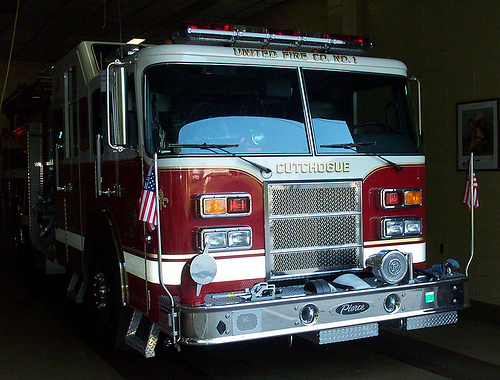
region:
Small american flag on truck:
[136, 153, 182, 358]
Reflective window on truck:
[139, 68, 425, 159]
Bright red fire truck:
[11, 19, 492, 379]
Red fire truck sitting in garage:
[9, 11, 494, 360]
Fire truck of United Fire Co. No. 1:
[94, 17, 478, 367]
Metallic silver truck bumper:
[169, 266, 482, 362]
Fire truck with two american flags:
[65, 19, 496, 369]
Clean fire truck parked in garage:
[26, 13, 493, 374]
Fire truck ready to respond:
[46, 22, 478, 363]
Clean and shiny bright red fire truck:
[5, 11, 496, 336]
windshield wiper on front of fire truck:
[156, 128, 278, 188]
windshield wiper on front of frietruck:
[316, 133, 409, 175]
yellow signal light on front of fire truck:
[197, 180, 229, 220]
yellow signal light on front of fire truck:
[403, 182, 425, 212]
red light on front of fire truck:
[378, 177, 404, 213]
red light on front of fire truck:
[226, 188, 254, 218]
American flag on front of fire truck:
[136, 142, 176, 305]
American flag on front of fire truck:
[449, 130, 490, 322]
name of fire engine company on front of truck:
[228, 32, 378, 80]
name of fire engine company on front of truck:
[262, 144, 408, 211]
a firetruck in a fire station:
[8, 9, 491, 364]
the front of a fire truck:
[138, 22, 488, 354]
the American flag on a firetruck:
[131, 148, 166, 249]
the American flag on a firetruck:
[463, 143, 483, 233]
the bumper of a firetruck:
[176, 272, 473, 352]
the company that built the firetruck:
[326, 296, 373, 321]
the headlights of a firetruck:
[199, 227, 256, 248]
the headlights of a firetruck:
[378, 218, 432, 241]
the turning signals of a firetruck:
[194, 190, 258, 220]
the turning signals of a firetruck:
[378, 183, 425, 208]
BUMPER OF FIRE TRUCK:
[177, 276, 478, 343]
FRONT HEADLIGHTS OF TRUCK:
[197, 221, 254, 247]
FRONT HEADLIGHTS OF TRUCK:
[380, 215, 430, 235]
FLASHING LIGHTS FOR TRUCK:
[196, 186, 253, 216]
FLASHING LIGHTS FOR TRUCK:
[375, 185, 425, 210]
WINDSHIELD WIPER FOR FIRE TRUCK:
[156, 130, 246, 155]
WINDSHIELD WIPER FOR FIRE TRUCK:
[320, 140, 401, 156]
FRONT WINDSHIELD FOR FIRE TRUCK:
[140, 57, 312, 159]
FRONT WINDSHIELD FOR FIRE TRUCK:
[294, 57, 433, 162]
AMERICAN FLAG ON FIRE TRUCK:
[133, 146, 164, 236]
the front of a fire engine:
[34, 22, 477, 367]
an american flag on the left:
[115, 123, 205, 284]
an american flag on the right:
[444, 142, 481, 308]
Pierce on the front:
[326, 296, 384, 327]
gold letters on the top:
[212, 37, 379, 78]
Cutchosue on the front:
[259, 149, 361, 185]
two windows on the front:
[142, 57, 433, 162]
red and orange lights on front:
[196, 180, 433, 212]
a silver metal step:
[93, 308, 190, 367]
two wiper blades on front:
[160, 129, 418, 179]